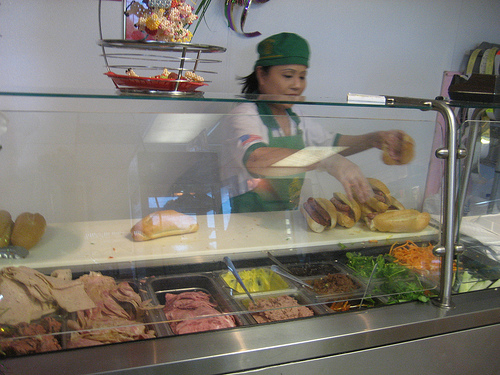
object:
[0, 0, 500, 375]
photograph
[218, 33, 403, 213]
woman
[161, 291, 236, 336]
meat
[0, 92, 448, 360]
plastic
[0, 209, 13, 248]
food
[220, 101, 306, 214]
apron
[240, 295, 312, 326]
garnishes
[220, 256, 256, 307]
spoons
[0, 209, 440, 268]
counter top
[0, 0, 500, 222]
walls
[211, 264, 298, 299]
container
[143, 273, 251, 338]
containers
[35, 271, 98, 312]
deli meat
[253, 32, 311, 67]
hat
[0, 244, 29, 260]
tongs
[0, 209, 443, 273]
counter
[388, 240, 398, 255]
carrots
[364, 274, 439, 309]
vegetables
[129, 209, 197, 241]
bread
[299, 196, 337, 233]
sandwich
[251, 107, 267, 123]
green and white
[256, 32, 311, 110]
head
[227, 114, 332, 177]
arm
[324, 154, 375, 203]
hand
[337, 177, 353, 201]
fingers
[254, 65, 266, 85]
ear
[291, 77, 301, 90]
nose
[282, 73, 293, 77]
eye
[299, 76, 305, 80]
eye